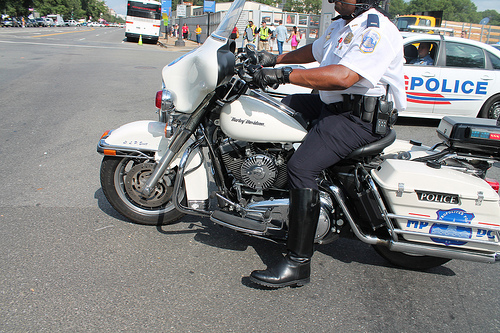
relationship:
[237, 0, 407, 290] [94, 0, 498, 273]
officer sitting on motorcycle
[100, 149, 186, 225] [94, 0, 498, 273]
front wheel of motorcycle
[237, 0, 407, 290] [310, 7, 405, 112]
officer wearing shirt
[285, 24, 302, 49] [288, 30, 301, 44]
woman wearing top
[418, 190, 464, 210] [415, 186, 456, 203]
lettering on background